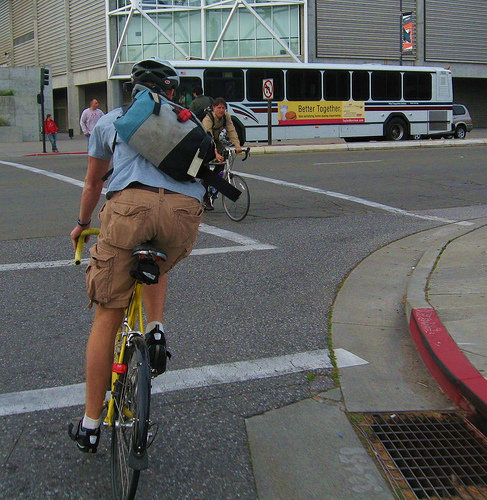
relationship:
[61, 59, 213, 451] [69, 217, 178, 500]
man riding bike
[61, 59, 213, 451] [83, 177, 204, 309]
man wearing shorts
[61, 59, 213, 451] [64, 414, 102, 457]
man has shoe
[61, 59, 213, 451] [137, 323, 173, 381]
man has shoe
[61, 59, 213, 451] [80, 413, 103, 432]
man wearing sock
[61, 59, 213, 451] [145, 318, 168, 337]
man wearing sock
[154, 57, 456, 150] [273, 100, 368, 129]
bus has sign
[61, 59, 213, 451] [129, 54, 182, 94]
man wearing helmet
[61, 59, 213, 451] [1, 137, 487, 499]
man crossing road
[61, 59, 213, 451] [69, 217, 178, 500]
man on bike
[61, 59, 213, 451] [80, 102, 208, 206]
man wearing shirt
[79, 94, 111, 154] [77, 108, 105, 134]
man in sweatshirt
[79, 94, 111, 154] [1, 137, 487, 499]
man crossing road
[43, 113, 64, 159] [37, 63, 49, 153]
woman against pole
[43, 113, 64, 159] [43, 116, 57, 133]
woman wearing sweatshirt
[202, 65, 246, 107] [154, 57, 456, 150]
window on bus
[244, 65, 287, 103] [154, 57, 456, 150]
window on bus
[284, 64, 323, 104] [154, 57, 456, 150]
window on bus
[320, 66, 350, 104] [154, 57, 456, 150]
window on bus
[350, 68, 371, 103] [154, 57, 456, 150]
window on bus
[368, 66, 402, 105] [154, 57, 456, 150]
window on bus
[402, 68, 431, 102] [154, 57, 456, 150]
window on bus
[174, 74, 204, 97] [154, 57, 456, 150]
window on bus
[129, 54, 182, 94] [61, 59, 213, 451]
helmet on man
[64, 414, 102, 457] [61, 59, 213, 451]
shoe of man